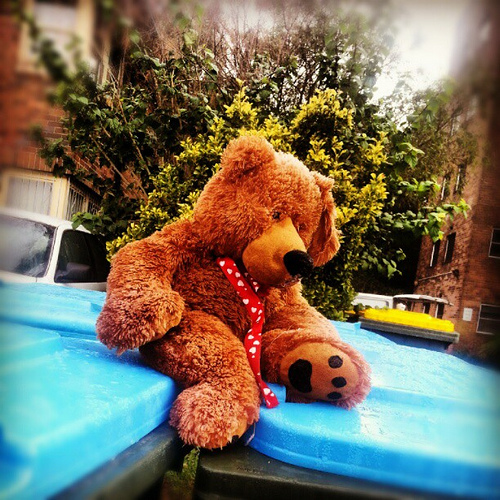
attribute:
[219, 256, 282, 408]
ribbon — red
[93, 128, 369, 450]
stuffed bear — large, brown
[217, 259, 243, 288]
hearts — white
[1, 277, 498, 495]
lids — blue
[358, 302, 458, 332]
lid — yellow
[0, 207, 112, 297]
vehicle — white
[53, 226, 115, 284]
window — tinted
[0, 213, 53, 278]
window — tinted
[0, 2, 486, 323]
shrubs — over grown, green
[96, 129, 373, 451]
bear — stuffed, brown, plush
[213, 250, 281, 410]
ribbon — red, red and white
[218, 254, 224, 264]
heart — white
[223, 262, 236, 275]
heart — white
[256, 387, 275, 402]
heart — white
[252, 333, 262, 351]
heart — white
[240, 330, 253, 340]
heart — white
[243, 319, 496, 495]
bench seat — blue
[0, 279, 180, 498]
bench seat — blue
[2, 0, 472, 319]
leaves — green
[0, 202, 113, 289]
car — white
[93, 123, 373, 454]
teddy bear — brown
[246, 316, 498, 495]
table — blue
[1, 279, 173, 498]
table — blue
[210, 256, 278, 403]
neck collar — white, red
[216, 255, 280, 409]
tie — red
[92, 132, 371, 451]
fur — brown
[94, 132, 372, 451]
stuffed animal — toy